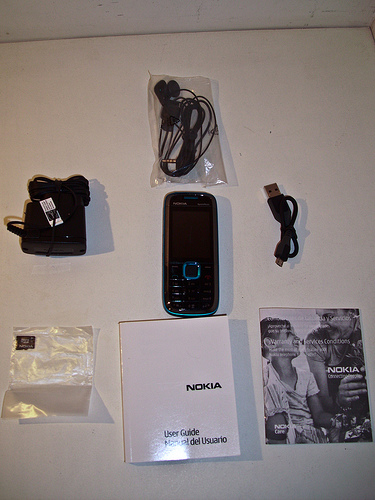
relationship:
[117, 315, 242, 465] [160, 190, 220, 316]
user guide for phone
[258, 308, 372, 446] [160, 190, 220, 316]
warranty book for phone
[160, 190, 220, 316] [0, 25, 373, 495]
phone on top of table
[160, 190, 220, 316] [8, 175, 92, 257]
phone has charger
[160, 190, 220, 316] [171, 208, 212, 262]
phone has screen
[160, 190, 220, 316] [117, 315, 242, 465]
phone has user guide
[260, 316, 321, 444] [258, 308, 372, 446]
person on front of warranty book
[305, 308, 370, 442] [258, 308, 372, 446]
person on front of warranty book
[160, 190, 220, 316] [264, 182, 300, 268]
phone has connector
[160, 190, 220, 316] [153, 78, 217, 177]
phone has earphones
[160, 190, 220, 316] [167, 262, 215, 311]
phone has keypad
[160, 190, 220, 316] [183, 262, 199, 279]
phone has button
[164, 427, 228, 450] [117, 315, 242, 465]
writing on front of user guide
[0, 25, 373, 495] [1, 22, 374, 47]
table has edge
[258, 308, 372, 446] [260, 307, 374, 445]
warranty book has picture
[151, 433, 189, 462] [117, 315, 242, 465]
light reflected on user guide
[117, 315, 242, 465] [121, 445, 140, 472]
user guide has corner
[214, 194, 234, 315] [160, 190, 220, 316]
shadow under phone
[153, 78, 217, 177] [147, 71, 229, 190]
earphones inside of bag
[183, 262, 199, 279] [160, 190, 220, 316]
button in middle of phone